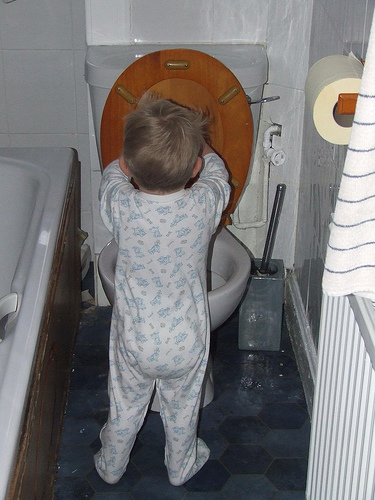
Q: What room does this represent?
A: It represents the bathroom.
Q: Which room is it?
A: It is a bathroom.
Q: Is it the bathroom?
A: Yes, it is the bathroom.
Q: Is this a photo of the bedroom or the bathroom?
A: It is showing the bathroom.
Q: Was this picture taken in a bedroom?
A: No, the picture was taken in a bathroom.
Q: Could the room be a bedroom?
A: No, it is a bathroom.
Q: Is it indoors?
A: Yes, it is indoors.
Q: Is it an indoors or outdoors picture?
A: It is indoors.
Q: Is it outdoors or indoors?
A: It is indoors.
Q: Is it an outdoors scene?
A: No, it is indoors.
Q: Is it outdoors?
A: No, it is indoors.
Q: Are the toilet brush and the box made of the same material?
A: Yes, both the toilet brush and the box are made of metal.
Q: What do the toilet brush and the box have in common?
A: The material, both the toilet brush and the box are metallic.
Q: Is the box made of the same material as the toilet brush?
A: Yes, both the box and the toilet brush are made of metal.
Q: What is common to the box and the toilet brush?
A: The material, both the box and the toilet brush are metallic.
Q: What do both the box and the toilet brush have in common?
A: The material, both the box and the toilet brush are metallic.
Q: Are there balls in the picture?
A: No, there are no balls.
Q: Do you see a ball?
A: No, there are no balls.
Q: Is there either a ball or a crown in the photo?
A: No, there are no balls or crowns.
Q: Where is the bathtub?
A: The bathtub is in the bathroom.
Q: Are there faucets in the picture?
A: No, there are no faucets.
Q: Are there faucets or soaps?
A: No, there are no faucets or soaps.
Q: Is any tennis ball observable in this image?
A: No, there are no tennis balls.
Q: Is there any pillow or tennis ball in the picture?
A: No, there are no tennis balls or pillows.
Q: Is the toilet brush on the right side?
A: Yes, the toilet brush is on the right of the image.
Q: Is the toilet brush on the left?
A: No, the toilet brush is on the right of the image.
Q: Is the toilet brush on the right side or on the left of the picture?
A: The toilet brush is on the right of the image.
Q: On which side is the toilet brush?
A: The toilet brush is on the right of the image.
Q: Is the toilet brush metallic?
A: Yes, the toilet brush is metallic.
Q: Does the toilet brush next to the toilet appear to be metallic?
A: Yes, the toilet brush is metallic.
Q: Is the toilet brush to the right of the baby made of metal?
A: Yes, the toilet brush is made of metal.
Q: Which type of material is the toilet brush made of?
A: The toilet brush is made of metal.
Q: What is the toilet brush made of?
A: The toilet brush is made of metal.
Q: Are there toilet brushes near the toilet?
A: Yes, there is a toilet brush near the toilet.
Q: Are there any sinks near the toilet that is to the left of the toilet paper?
A: No, there is a toilet brush near the toilet.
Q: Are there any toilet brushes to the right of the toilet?
A: Yes, there is a toilet brush to the right of the toilet.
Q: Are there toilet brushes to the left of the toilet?
A: No, the toilet brush is to the right of the toilet.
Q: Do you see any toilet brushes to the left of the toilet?
A: No, the toilet brush is to the right of the toilet.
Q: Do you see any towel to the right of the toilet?
A: No, there is a toilet brush to the right of the toilet.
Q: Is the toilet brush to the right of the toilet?
A: Yes, the toilet brush is to the right of the toilet.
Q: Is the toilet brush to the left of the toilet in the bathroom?
A: No, the toilet brush is to the right of the toilet.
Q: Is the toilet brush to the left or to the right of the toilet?
A: The toilet brush is to the right of the toilet.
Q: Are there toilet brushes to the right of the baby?
A: Yes, there is a toilet brush to the right of the baby.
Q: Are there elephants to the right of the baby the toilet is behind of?
A: No, there is a toilet brush to the right of the baby.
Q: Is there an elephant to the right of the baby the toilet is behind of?
A: No, there is a toilet brush to the right of the baby.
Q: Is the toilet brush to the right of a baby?
A: Yes, the toilet brush is to the right of a baby.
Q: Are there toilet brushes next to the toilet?
A: Yes, there is a toilet brush next to the toilet.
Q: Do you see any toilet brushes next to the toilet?
A: Yes, there is a toilet brush next to the toilet.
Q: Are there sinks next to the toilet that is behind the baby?
A: No, there is a toilet brush next to the toilet.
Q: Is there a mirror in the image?
A: No, there are no mirrors.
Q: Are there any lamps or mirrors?
A: No, there are no mirrors or lamps.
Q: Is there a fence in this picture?
A: No, there are no fences.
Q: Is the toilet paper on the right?
A: Yes, the toilet paper is on the right of the image.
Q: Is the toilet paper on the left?
A: No, the toilet paper is on the right of the image.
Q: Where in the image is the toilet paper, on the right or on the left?
A: The toilet paper is on the right of the image.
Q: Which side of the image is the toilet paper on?
A: The toilet paper is on the right of the image.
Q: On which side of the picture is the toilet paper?
A: The toilet paper is on the right of the image.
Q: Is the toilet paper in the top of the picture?
A: Yes, the toilet paper is in the top of the image.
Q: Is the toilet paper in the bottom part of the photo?
A: No, the toilet paper is in the top of the image.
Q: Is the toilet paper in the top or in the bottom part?
A: The toilet paper is in the top of the image.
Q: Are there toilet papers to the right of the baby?
A: Yes, there is a toilet paper to the right of the baby.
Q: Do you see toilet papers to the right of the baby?
A: Yes, there is a toilet paper to the right of the baby.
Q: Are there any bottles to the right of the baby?
A: No, there is a toilet paper to the right of the baby.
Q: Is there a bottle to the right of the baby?
A: No, there is a toilet paper to the right of the baby.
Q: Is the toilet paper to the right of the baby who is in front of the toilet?
A: Yes, the toilet paper is to the right of the baby.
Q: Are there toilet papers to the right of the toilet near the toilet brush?
A: Yes, there is a toilet paper to the right of the toilet.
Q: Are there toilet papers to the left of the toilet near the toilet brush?
A: No, the toilet paper is to the right of the toilet.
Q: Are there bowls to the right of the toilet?
A: No, there is a toilet paper to the right of the toilet.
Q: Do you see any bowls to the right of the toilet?
A: No, there is a toilet paper to the right of the toilet.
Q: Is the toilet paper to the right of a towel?
A: No, the toilet paper is to the right of the toilet.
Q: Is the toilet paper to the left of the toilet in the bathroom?
A: No, the toilet paper is to the right of the toilet.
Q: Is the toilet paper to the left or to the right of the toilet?
A: The toilet paper is to the right of the toilet.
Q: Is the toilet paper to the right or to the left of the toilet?
A: The toilet paper is to the right of the toilet.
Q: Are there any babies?
A: Yes, there is a baby.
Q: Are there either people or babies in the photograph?
A: Yes, there is a baby.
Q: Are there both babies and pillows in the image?
A: No, there is a baby but no pillows.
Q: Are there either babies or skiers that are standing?
A: Yes, the baby is standing.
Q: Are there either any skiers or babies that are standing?
A: Yes, the baby is standing.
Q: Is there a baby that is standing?
A: Yes, there is a baby that is standing.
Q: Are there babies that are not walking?
A: Yes, there is a baby that is standing.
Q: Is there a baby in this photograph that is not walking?
A: Yes, there is a baby that is standing.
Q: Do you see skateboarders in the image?
A: No, there are no skateboarders.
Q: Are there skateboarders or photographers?
A: No, there are no skateboarders or photographers.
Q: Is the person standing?
A: Yes, the baby is standing.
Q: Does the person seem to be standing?
A: Yes, the baby is standing.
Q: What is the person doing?
A: The baby is standing.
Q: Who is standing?
A: The baby is standing.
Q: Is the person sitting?
A: No, the baby is standing.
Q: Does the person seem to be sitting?
A: No, the baby is standing.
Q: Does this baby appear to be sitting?
A: No, the baby is standing.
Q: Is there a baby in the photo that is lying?
A: No, there is a baby but he is standing.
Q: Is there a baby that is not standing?
A: No, there is a baby but he is standing.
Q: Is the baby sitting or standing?
A: The baby is standing.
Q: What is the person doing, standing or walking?
A: The baby is standing.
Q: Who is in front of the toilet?
A: The baby is in front of the toilet.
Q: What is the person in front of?
A: The baby is in front of the toilet.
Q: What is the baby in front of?
A: The baby is in front of the toilet.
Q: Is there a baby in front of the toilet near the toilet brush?
A: Yes, there is a baby in front of the toilet.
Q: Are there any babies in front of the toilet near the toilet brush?
A: Yes, there is a baby in front of the toilet.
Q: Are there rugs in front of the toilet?
A: No, there is a baby in front of the toilet.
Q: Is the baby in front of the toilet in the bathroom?
A: Yes, the baby is in front of the toilet.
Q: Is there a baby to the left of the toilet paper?
A: Yes, there is a baby to the left of the toilet paper.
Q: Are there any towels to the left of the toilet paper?
A: No, there is a baby to the left of the toilet paper.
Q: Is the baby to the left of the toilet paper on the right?
A: Yes, the baby is to the left of the toilet paper.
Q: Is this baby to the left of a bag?
A: No, the baby is to the left of the toilet paper.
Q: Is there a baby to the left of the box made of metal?
A: Yes, there is a baby to the left of the box.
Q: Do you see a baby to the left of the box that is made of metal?
A: Yes, there is a baby to the left of the box.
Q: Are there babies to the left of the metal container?
A: Yes, there is a baby to the left of the box.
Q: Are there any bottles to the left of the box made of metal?
A: No, there is a baby to the left of the box.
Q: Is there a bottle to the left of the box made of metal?
A: No, there is a baby to the left of the box.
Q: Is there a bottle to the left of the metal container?
A: No, there is a baby to the left of the box.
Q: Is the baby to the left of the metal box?
A: Yes, the baby is to the left of the box.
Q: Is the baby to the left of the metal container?
A: Yes, the baby is to the left of the box.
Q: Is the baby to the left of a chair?
A: No, the baby is to the left of the box.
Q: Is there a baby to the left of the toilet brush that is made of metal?
A: Yes, there is a baby to the left of the toilet brush.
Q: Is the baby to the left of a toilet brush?
A: Yes, the baby is to the left of a toilet brush.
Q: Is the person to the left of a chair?
A: No, the baby is to the left of a toilet brush.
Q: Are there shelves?
A: No, there are no shelves.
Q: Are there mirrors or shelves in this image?
A: No, there are no shelves or mirrors.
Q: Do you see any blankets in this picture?
A: No, there are no blankets.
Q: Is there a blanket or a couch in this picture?
A: No, there are no blankets or couches.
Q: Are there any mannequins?
A: No, there are no mannequins.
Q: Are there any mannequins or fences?
A: No, there are no mannequins or fences.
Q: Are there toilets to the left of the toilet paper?
A: Yes, there is a toilet to the left of the toilet paper.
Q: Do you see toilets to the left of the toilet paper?
A: Yes, there is a toilet to the left of the toilet paper.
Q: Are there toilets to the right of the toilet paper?
A: No, the toilet is to the left of the toilet paper.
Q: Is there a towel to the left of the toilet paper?
A: No, there is a toilet to the left of the toilet paper.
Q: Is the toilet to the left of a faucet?
A: No, the toilet is to the left of the toilet paper.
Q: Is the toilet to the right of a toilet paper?
A: No, the toilet is to the left of a toilet paper.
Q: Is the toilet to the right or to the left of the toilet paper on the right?
A: The toilet is to the left of the toilet paper.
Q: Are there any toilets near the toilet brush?
A: Yes, there is a toilet near the toilet brush.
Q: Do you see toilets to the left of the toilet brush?
A: Yes, there is a toilet to the left of the toilet brush.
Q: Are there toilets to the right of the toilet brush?
A: No, the toilet is to the left of the toilet brush.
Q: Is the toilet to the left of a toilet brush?
A: Yes, the toilet is to the left of a toilet brush.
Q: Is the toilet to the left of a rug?
A: No, the toilet is to the left of a toilet brush.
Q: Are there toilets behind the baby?
A: Yes, there is a toilet behind the baby.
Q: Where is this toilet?
A: The toilet is in the bathroom.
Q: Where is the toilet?
A: The toilet is in the bathroom.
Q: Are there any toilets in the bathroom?
A: Yes, there is a toilet in the bathroom.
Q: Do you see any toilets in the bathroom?
A: Yes, there is a toilet in the bathroom.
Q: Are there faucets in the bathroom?
A: No, there is a toilet in the bathroom.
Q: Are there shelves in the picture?
A: No, there are no shelves.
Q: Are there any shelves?
A: No, there are no shelves.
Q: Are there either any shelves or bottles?
A: No, there are no shelves or bottles.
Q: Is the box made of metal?
A: Yes, the box is made of metal.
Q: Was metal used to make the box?
A: Yes, the box is made of metal.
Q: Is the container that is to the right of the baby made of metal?
A: Yes, the box is made of metal.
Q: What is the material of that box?
A: The box is made of metal.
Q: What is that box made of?
A: The box is made of metal.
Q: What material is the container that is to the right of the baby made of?
A: The box is made of metal.